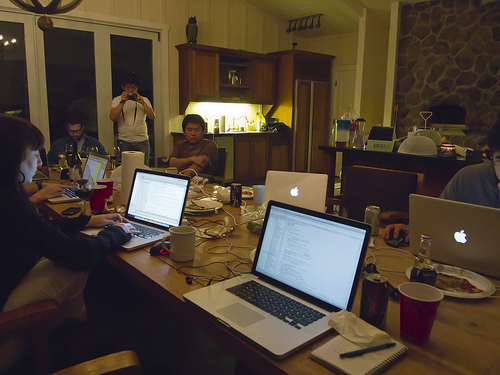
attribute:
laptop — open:
[76, 169, 193, 256]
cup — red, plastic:
[397, 280, 445, 343]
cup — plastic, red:
[84, 178, 109, 218]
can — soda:
[360, 272, 390, 329]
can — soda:
[228, 180, 242, 207]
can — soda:
[364, 202, 380, 234]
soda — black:
[339, 258, 405, 350]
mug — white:
[150, 207, 207, 272]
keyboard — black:
[231, 279, 324, 331]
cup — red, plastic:
[97, 175, 114, 196]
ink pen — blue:
[330, 334, 397, 365]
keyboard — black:
[225, 279, 325, 329]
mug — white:
[161, 220, 203, 266]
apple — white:
[291, 185, 297, 199]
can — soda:
[358, 270, 390, 322]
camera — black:
[119, 88, 135, 101]